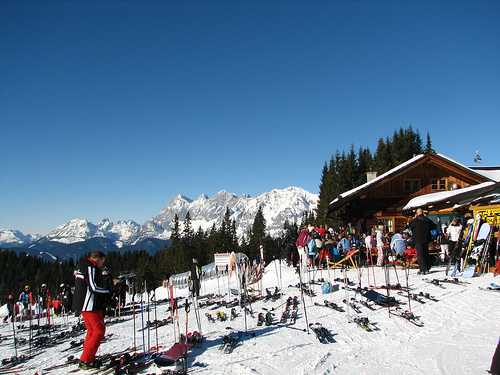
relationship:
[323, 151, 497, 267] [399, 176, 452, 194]
lodge has windows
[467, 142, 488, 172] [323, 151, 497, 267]
lift above lodge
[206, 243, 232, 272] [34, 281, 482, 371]
sign in snow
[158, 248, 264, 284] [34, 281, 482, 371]
greenhouse in snow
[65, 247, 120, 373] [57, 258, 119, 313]
man wearing coat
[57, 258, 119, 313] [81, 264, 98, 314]
coat has stripes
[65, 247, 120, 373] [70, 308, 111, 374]
man has pants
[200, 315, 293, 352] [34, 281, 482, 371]
shadow on snow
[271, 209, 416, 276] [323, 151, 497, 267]
crowd outside of lodge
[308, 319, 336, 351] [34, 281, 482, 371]
skis on ground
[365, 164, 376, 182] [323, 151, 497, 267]
chimney on lodge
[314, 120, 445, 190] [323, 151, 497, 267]
trees behind lodge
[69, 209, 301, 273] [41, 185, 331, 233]
trees in front of mountains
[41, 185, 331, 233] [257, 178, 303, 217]
mountains have snow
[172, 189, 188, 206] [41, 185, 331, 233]
peak on mountains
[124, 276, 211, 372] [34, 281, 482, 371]
poles at snow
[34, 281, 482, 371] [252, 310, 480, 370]
snow has tracks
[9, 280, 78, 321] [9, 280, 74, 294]
skiers have helmets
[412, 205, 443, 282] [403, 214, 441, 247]
man has coat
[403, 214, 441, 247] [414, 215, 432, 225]
coat has hood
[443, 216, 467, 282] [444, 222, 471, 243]
man has coat